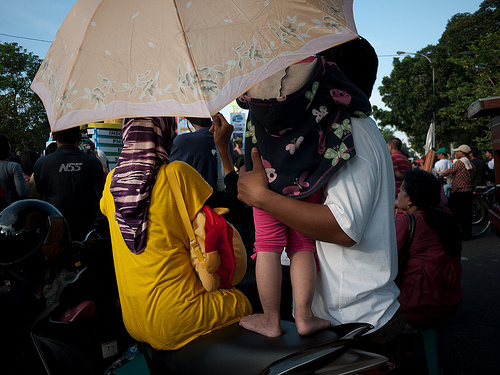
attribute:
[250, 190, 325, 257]
pants — pink 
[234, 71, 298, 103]
hood — white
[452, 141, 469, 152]
cap — brown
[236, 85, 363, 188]
hoodie — black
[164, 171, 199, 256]
strap — yellow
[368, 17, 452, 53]
sky — blue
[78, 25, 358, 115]
leaves — green, white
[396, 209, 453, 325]
dress — red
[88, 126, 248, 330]
woman — long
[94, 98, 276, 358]
pants — pink 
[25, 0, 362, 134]
umbrella — tan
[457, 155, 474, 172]
napkin — white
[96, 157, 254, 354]
dress — yellow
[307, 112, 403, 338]
t-shirt — white